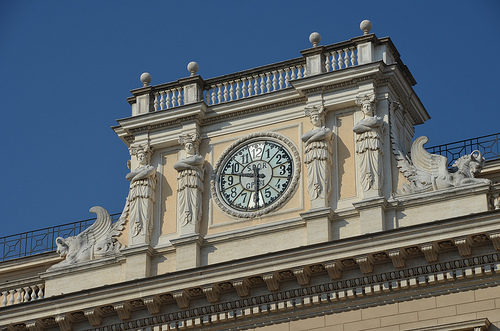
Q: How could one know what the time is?
A: Clock.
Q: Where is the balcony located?
A: Over clock.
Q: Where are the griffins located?
A: Far sides of clock.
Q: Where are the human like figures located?
A: Sides of clock.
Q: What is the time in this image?
A: 6:47.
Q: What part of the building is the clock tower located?
A: Top.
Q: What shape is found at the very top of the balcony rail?
A: Circles.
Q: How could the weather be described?
A: Clear.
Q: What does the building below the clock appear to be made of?
A: Brick.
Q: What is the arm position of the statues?
A: Crossed.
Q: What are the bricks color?
A: Beige.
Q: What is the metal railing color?
A: Black.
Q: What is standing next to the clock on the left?
A: Two statues.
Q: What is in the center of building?
A: A clock.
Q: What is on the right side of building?
A: Statue of winged creature.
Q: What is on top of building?
A: Balcony.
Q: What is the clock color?
A: Black and blue.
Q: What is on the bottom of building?
A: Bricks.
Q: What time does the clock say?
A: 6:47.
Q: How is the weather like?
A: Clear.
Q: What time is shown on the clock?
A: 5:47 P.M.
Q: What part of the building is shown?
A: The top and ledge.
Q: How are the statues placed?
A: On both sides of the building.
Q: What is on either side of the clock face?
A: Statues.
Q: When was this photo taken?
A: During the day.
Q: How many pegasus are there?
A: 2.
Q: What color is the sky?
A: Blue.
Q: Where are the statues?
A: On either side of the clock.